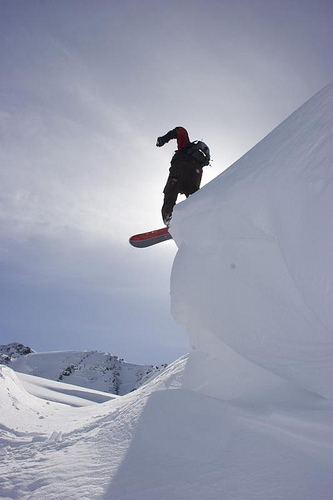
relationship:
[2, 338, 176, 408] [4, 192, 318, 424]
hills in distance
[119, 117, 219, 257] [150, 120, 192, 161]
snowboarder has arm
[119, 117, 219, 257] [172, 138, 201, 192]
snowboarder wearing backpack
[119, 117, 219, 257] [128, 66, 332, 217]
snowboarder on top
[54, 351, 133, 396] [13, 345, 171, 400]
foliage on hill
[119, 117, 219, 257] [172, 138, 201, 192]
snowboarder has backpack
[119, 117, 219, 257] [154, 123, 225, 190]
snowboarder wearing jacket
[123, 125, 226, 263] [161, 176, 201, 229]
person wearing pants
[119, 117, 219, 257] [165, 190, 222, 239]
snowboarder on ledge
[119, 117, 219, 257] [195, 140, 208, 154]
snowboarder wearing helmet